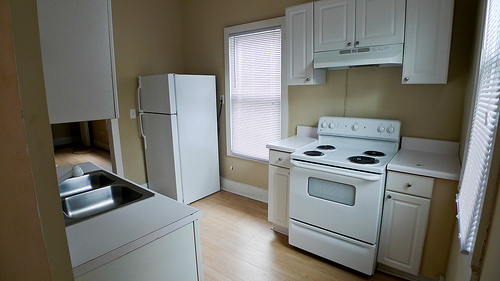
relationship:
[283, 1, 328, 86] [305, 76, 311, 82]
cabinet has knob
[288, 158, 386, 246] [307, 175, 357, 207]
oven has window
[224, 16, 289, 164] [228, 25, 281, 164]
blinds with blinds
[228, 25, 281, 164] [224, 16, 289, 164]
blinds covering blinds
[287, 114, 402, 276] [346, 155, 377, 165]
stove has burner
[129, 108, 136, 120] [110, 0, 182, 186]
light switch installed on wall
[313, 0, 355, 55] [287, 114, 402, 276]
cabinet over stove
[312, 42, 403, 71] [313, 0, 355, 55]
hood under cabinet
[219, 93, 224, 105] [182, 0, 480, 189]
outlet installed on wall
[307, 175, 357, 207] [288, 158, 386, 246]
window on front of oven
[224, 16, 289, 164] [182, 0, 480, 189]
blinds on middle of wall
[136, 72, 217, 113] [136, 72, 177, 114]
freezer has door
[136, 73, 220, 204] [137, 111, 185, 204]
freezer has door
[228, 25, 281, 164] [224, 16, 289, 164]
blinds hanging on blinds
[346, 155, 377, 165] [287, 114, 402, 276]
burner on top of stove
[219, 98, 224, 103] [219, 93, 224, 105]
refridgerator plug plugged in outlet